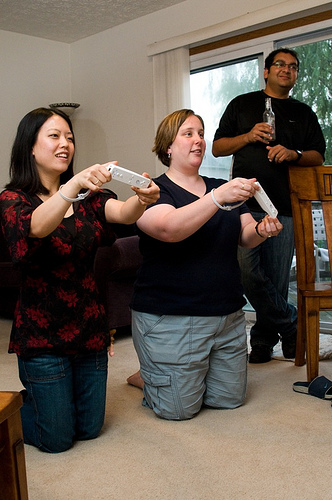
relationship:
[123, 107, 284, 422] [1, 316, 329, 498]
lady on carpet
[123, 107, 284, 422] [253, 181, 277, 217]
lady holds wii remote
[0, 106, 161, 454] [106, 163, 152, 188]
asian girl holds wii remote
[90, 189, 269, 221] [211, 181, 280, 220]
white wii wii remote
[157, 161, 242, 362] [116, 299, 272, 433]
lady on her knees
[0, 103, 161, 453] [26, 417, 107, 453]
asian girl playing a video game on her knees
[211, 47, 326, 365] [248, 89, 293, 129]
man in eyeglasses drinking a bottle of beer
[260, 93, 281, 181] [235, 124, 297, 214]
beer bottle man holding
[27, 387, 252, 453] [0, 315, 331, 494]
knees kneeling on floor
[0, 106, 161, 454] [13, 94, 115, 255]
asian girl with long hair smiling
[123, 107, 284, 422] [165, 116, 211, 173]
lady with short hair smiling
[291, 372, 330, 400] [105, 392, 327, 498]
slipper on floor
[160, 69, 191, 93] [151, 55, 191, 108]
white vertical blinds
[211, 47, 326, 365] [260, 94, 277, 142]
man holding bottle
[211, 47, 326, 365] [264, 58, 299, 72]
man wears eyeglasses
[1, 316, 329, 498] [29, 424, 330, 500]
carpet on a room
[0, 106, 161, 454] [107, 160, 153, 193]
asian girl holding and playing wii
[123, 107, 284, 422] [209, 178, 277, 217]
lady kneeling playing and holding wii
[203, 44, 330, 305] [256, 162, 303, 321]
man holding coke bottle standing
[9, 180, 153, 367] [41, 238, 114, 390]
shirt with red flowers on woman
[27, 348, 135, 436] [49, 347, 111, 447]
jeans on woman who kneeling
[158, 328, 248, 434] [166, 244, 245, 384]
pants on blond woman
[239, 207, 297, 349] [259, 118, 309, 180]
jeans on standing man